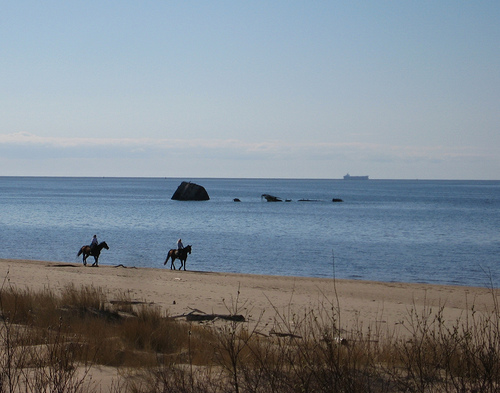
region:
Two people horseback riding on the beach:
[71, 230, 192, 271]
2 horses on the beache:
[68, 233, 220, 312]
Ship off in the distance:
[323, 170, 378, 188]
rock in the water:
[162, 175, 223, 205]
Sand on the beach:
[8, 253, 494, 342]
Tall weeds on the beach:
[6, 275, 488, 379]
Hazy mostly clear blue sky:
[3, 2, 495, 180]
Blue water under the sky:
[1, 172, 491, 284]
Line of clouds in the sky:
[6, 113, 488, 179]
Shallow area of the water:
[6, 194, 498, 249]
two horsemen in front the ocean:
[34, 175, 245, 297]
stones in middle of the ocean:
[156, 173, 352, 222]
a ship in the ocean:
[328, 164, 385, 189]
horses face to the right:
[72, 224, 201, 276]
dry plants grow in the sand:
[0, 267, 497, 392]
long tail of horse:
[162, 247, 172, 267]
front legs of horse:
[178, 262, 187, 272]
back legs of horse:
[168, 256, 178, 269]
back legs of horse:
[79, 252, 88, 265]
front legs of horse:
[91, 253, 102, 267]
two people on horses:
[83, 234, 193, 268]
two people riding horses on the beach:
[68, 218, 233, 284]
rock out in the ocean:
[159, 173, 239, 223]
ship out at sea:
[338, 168, 380, 186]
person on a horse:
[163, 231, 203, 286]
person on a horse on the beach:
[156, 221, 224, 288]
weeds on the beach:
[41, 287, 299, 388]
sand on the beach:
[256, 255, 415, 320]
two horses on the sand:
[68, 226, 225, 274]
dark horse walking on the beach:
[69, 236, 125, 261]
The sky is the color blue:
[41, 21, 437, 131]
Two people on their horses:
[68, 225, 206, 279]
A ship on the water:
[332, 163, 379, 184]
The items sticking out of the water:
[163, 176, 350, 211]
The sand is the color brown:
[246, 274, 472, 354]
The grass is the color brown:
[43, 291, 498, 391]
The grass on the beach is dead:
[78, 312, 495, 390]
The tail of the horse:
[158, 245, 174, 270]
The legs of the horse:
[167, 258, 189, 270]